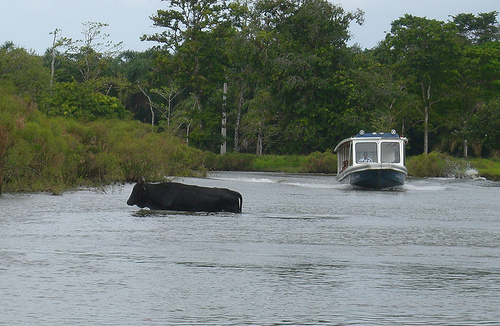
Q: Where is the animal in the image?
A: In the water.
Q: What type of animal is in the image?
A: A cow.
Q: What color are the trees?
A: Green.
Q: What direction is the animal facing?
A: Left.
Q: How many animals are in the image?
A: One.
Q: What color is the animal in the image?
A: Black.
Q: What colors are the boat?
A: Blue and white.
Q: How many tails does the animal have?
A: One.